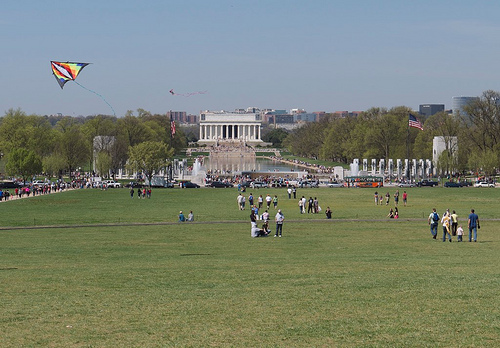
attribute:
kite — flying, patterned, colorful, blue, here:
[40, 47, 98, 101]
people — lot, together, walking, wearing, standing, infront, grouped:
[239, 176, 323, 260]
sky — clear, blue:
[119, 21, 260, 104]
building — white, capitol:
[189, 85, 257, 145]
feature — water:
[352, 143, 444, 178]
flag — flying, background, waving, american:
[400, 102, 426, 130]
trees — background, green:
[34, 99, 89, 144]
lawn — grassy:
[133, 223, 254, 313]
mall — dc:
[107, 73, 392, 226]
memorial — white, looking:
[166, 108, 301, 207]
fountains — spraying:
[338, 150, 404, 187]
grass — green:
[77, 236, 256, 337]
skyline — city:
[208, 97, 376, 138]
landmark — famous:
[197, 101, 415, 211]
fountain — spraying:
[365, 145, 446, 185]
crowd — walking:
[415, 195, 496, 262]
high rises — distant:
[380, 88, 482, 135]